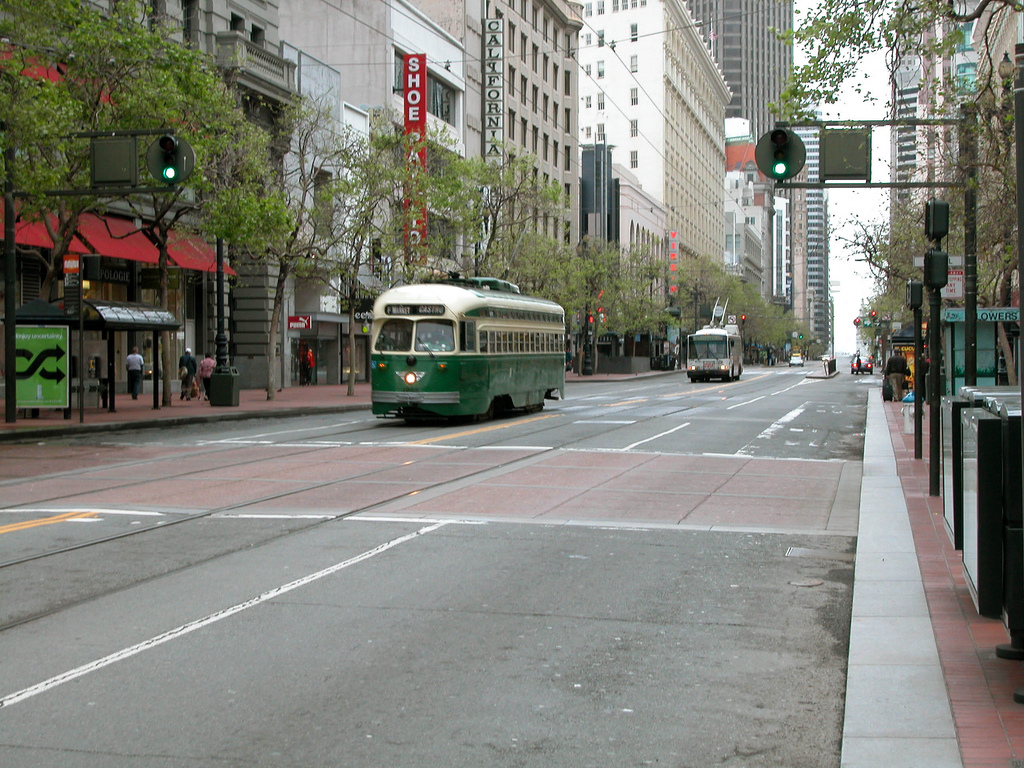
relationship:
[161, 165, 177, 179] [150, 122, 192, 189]
light on traffic signal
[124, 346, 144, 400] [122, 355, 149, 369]
person wearing shirt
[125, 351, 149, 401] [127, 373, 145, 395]
person wearing pants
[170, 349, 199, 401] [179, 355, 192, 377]
person wearing shirt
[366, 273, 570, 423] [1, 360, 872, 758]
bus driving on road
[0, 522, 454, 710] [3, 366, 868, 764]
line on pavement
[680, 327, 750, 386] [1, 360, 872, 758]
bus on road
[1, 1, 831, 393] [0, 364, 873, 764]
buildings line street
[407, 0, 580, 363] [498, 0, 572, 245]
building has lots of windows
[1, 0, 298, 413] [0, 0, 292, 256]
tree has leaves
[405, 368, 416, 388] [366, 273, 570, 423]
light on bus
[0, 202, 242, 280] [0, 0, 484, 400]
awning on building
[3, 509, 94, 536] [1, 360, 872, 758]
line on road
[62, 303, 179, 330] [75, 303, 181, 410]
canopy over bus stop